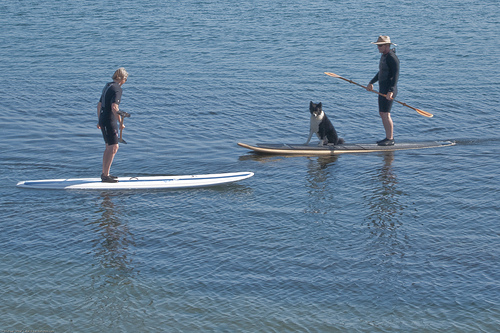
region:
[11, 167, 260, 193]
white and blue surfboard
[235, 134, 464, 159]
black and brown surfboard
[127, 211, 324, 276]
ripples in water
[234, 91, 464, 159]
dog sitting on surfboard in body of water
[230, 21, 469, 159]
person and dog standing on surfboard in water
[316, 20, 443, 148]
man holding row paddle while standing on surfboard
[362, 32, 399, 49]
fedora hat on man standing on surfboard in water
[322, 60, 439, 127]
brown and black row paddle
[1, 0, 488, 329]
body of blue tinted water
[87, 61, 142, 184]
person standing on white and blue surfboard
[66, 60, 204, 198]
man paddle boarding on board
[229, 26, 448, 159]
man paddle boarding on board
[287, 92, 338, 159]
black and white dog on board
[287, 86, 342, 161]
black and white dog on paddleboard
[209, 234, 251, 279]
ripples in blue and white water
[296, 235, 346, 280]
ripples in blue and white water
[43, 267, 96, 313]
ripples in blue and white water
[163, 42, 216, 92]
ripples in blue and white water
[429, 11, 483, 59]
ripples in blue and white water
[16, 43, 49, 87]
ripples in blue and white water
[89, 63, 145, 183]
Man on a board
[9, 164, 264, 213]
Board on the water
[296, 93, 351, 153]
Dog on a board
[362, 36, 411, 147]
Man standing on a board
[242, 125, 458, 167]
Board on the water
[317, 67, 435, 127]
Paddle in man's hand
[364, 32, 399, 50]
Hat on man's head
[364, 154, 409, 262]
Reflection on the water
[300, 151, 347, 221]
Reflection on the water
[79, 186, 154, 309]
Reflection on the water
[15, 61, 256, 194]
A person on a surfboard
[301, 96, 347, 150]
A black and white dog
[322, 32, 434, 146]
Man holding an oar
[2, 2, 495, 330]
The water appears calm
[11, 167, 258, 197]
The surfboard is white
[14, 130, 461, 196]
Two surfboards floating in the water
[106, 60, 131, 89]
Person has blonde hair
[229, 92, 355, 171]
A dog on a surfboard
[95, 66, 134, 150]
Person wearing a black outfit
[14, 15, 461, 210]
people and dog on boat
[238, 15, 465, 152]
man with dog on board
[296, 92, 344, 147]
dog on the board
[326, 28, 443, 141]
man on the board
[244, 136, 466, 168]
board with man and dog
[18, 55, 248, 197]
person on the board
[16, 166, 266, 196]
board with person on it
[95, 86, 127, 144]
wet suit on person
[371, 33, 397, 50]
hat on man on board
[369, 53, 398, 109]
suit on man on board